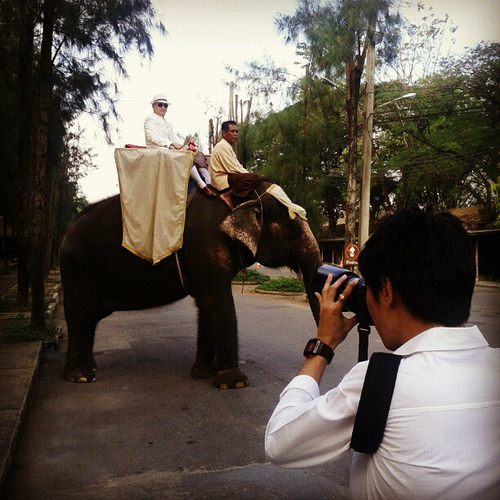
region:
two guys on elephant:
[50, 87, 330, 390]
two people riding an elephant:
[52, 87, 330, 392]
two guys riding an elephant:
[52, 90, 328, 394]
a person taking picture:
[262, 201, 497, 498]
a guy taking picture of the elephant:
[53, 90, 495, 497]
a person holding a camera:
[258, 200, 493, 495]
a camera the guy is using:
[309, 260, 368, 329]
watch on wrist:
[301, 335, 337, 366]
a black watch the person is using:
[299, 333, 336, 365]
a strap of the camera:
[346, 326, 408, 462]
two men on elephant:
[100, 88, 316, 395]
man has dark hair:
[217, 121, 237, 190]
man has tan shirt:
[202, 113, 235, 181]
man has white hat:
[147, 89, 179, 101]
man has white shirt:
[144, 103, 168, 145]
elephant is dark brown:
[68, 188, 263, 377]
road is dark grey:
[115, 401, 202, 493]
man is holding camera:
[288, 218, 443, 498]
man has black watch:
[306, 335, 343, 381]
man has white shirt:
[280, 340, 483, 498]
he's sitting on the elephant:
[213, 175, 256, 214]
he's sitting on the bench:
[143, 140, 164, 159]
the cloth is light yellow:
[135, 167, 153, 192]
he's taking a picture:
[315, 262, 386, 314]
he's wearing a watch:
[303, 334, 331, 365]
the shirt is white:
[417, 389, 442, 412]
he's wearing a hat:
[151, 92, 168, 107]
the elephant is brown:
[193, 218, 210, 239]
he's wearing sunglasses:
[156, 101, 171, 111]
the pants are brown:
[235, 172, 255, 187]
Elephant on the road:
[56, 175, 323, 390]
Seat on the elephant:
[112, 142, 209, 263]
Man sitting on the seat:
[143, 92, 215, 198]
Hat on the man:
[148, 93, 170, 108]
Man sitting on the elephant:
[207, 119, 254, 194]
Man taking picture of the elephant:
[264, 207, 497, 498]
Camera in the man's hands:
[308, 259, 375, 329]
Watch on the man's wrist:
[302, 336, 335, 365]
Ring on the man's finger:
[333, 290, 348, 302]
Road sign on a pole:
[341, 242, 359, 267]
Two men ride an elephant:
[56, 94, 345, 384]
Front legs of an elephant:
[191, 276, 254, 389]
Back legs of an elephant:
[61, 310, 108, 381]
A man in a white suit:
[144, 91, 184, 149]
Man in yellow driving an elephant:
[208, 120, 251, 190]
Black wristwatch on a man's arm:
[302, 336, 334, 363]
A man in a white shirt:
[263, 207, 498, 497]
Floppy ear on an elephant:
[221, 199, 263, 256]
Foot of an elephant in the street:
[210, 367, 251, 390]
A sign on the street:
[345, 240, 359, 263]